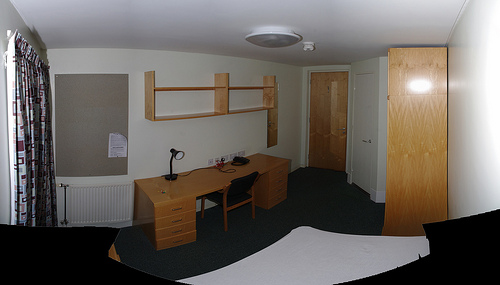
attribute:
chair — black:
[196, 170, 258, 233]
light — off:
[242, 29, 303, 49]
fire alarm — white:
[301, 41, 316, 51]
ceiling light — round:
[240, 25, 304, 52]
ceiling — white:
[12, 1, 460, 67]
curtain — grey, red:
[12, 30, 76, 248]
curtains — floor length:
[13, 31, 60, 251]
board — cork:
[59, 73, 187, 171]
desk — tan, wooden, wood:
[132, 148, 292, 247]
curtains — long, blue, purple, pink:
[8, 30, 63, 223]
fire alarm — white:
[297, 38, 321, 53]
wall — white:
[112, 48, 372, 250]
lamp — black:
[163, 147, 185, 179]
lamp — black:
[158, 146, 180, 200]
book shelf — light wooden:
[137, 65, 279, 116]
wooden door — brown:
[309, 71, 351, 171]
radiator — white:
[61, 179, 135, 231]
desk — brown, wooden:
[126, 155, 301, 255]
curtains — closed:
[10, 21, 81, 247]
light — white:
[238, 23, 304, 50]